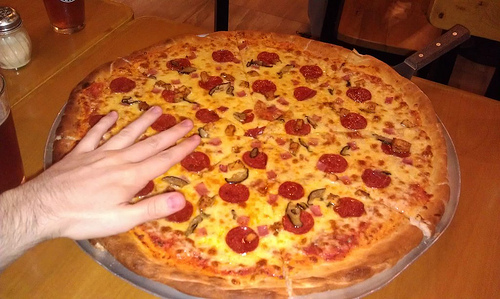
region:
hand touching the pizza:
[24, 100, 199, 230]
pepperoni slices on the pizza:
[94, 37, 409, 247]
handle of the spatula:
[390, 21, 469, 76]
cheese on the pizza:
[101, 50, 412, 252]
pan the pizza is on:
[42, 62, 467, 298]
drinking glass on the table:
[45, 2, 87, 36]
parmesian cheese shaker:
[2, 6, 31, 67]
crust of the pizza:
[41, 36, 461, 298]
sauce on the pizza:
[89, 43, 431, 264]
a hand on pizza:
[23, 96, 198, 253]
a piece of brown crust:
[299, 262, 439, 297]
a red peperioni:
[254, 41, 281, 66]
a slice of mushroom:
[286, 200, 306, 227]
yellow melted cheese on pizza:
[205, 217, 222, 245]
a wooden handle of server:
[406, 9, 467, 79]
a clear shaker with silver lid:
[1, 0, 37, 96]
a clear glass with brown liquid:
[36, 0, 94, 45]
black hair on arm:
[16, 174, 73, 229]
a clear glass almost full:
[0, 96, 50, 186]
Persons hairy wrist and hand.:
[0, 104, 201, 267]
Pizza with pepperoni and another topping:
[50, 27, 447, 297]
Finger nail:
[165, 191, 184, 211]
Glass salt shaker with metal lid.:
[0, 7, 33, 71]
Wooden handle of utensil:
[392, 22, 469, 81]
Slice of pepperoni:
[225, 225, 258, 255]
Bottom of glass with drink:
[44, 0, 86, 35]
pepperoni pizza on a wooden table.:
[0, 15, 498, 297]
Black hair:
[0, 184, 47, 264]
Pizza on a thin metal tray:
[42, 28, 460, 298]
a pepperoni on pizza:
[222, 221, 262, 261]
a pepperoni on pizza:
[276, 205, 313, 236]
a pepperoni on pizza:
[280, 173, 305, 201]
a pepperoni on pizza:
[220, 171, 250, 201]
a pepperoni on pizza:
[317, 148, 347, 176]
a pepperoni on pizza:
[340, 195, 365, 219]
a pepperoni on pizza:
[359, 165, 394, 191]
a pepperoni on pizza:
[179, 147, 211, 173]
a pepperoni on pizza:
[242, 138, 270, 173]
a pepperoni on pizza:
[283, 110, 310, 142]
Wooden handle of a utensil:
[406, 24, 470, 71]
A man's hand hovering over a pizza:
[0, 107, 200, 264]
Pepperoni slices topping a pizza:
[112, 57, 414, 249]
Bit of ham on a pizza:
[196, 175, 213, 197]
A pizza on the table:
[57, 24, 455, 289]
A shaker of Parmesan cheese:
[0, 8, 36, 67]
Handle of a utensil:
[406, 23, 469, 70]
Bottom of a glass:
[41, 0, 90, 37]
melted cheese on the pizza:
[236, 141, 313, 239]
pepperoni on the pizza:
[285, 211, 315, 241]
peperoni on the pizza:
[325, 188, 367, 217]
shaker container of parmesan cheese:
[1, 5, 34, 70]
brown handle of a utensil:
[392, 23, 469, 80]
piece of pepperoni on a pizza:
[109, 75, 135, 92]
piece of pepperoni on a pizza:
[227, 224, 257, 251]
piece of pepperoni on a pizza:
[283, 119, 309, 135]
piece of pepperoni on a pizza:
[300, 62, 322, 79]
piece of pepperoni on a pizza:
[211, 48, 232, 63]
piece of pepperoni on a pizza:
[278, 178, 302, 199]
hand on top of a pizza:
[1, 100, 200, 260]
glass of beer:
[0, 82, 25, 192]